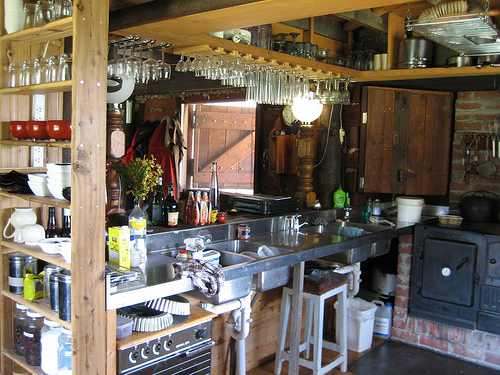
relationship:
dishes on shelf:
[7, 119, 74, 139] [1, 138, 74, 148]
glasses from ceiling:
[107, 33, 175, 86] [114, 0, 407, 52]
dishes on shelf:
[25, 162, 73, 200] [1, 189, 68, 212]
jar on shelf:
[20, 311, 41, 365] [1, 345, 42, 375]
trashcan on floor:
[333, 293, 378, 353] [252, 321, 499, 374]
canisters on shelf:
[7, 253, 76, 375] [1, 345, 42, 375]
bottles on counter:
[152, 174, 180, 224] [120, 192, 333, 233]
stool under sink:
[273, 275, 353, 373] [298, 221, 400, 262]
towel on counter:
[173, 259, 232, 299] [110, 249, 199, 310]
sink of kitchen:
[298, 221, 400, 262] [1, 0, 500, 372]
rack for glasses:
[106, 31, 164, 51] [107, 33, 175, 86]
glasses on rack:
[107, 33, 175, 86] [106, 31, 164, 51]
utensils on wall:
[462, 130, 500, 175] [448, 91, 499, 208]